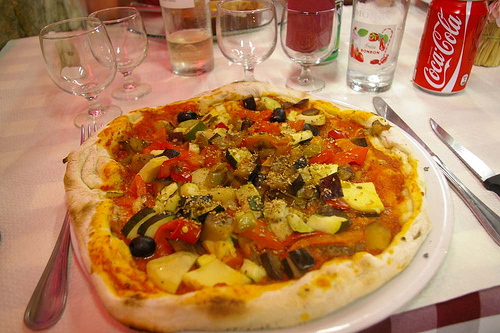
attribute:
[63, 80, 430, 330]
pizza — large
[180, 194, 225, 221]
vegetable — peppered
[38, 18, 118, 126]
glass — clear, empty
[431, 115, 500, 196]
knife — silver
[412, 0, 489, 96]
can — red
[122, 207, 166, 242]
zucchini — grilled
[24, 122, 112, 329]
fork — silver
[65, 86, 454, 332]
plate — white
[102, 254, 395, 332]
crust — thick, deep dish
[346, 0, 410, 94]
bottle — empty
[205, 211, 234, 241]
veggie — chopped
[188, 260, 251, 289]
squash — yellow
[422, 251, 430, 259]
spot — black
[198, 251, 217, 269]
pepper — yellow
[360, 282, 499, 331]
tablecloth — red